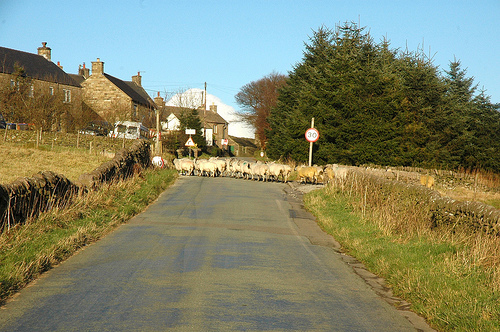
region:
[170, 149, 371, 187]
herd in the street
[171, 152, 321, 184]
white flock of sheeps in the middle of the road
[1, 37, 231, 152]
big houses in the left side of the road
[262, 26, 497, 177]
big green pines in the back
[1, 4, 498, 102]
light blue and clear sky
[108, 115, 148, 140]
white van parked in front of big house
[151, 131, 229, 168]
signboards on left side of the road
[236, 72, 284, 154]
little red tree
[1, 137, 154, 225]
dirt fence in left side of the road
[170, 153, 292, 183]
white wooly sheeps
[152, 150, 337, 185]
sheep cross the road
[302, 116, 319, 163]
sign gives speed limit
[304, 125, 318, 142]
sign is circular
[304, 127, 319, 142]
sign is attached to pole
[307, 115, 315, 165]
pole has sign attached to it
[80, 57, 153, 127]
house is in distance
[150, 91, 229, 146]
house is in distance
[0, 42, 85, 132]
house is in distance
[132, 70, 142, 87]
chimney is on top of house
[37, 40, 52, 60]
chimeny is on top of house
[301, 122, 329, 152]
sign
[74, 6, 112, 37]
white clouds in blue sky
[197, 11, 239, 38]
white clouds in blue sky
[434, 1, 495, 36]
white clouds in blue sky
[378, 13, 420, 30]
white clouds in blue sky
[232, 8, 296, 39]
white clouds in blue sky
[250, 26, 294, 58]
white clouds in blue sky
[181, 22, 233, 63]
white clouds in blue sky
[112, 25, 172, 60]
white clouds in blue sky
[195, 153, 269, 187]
white sheep crossing road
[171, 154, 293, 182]
Animals crossing the road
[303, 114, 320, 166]
Red and white road sign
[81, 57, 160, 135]
Brown rock building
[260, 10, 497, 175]
Tall, fat and green pine trees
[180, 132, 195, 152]
Triangle road sign for curve ahead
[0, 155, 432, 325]
Small narrow country road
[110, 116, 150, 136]
Parked white bus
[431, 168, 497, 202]
Empty green and brown grassy field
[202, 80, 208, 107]
Brown power pole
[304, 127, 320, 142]
Round sign with the number 30 on it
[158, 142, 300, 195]
sheep crossing the paved road from the field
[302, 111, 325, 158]
speed limit sign mounted on post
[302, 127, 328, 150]
white sign with red border and black text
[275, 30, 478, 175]
large green trees growing on side of road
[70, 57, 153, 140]
brown brick building with black roof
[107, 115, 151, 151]
black side of a large gray van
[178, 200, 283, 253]
dirt on the black paved road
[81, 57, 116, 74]
chimneys on top of the brick house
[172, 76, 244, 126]
large white cloud in the blue sky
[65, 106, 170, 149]
cars parked behind the grassy area